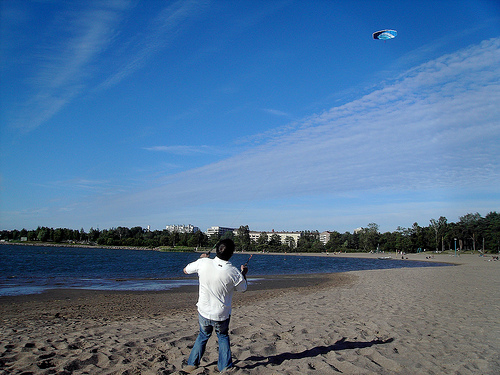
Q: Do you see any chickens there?
A: No, there are no chickens.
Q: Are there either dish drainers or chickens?
A: No, there are no chickens or dish drainers.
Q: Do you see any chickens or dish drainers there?
A: No, there are no chickens or dish drainers.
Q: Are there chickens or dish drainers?
A: No, there are no chickens or dish drainers.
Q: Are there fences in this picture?
A: No, there are no fences.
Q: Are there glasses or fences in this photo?
A: No, there are no fences or glasses.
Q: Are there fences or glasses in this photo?
A: No, there are no fences or glasses.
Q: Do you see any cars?
A: No, there are no cars.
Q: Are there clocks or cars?
A: No, there are no cars or clocks.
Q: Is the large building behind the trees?
A: Yes, the building is behind the trees.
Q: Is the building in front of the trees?
A: No, the building is behind the trees.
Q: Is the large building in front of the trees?
A: No, the building is behind the trees.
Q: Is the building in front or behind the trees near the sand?
A: The building is behind the trees.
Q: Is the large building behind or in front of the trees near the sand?
A: The building is behind the trees.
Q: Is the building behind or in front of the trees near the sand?
A: The building is behind the trees.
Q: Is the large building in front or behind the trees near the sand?
A: The building is behind the trees.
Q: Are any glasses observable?
A: No, there are no glasses.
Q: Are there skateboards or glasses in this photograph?
A: No, there are no glasses or skateboards.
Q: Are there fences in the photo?
A: No, there are no fences.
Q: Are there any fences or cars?
A: No, there are no fences or cars.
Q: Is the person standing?
A: Yes, the person is standing.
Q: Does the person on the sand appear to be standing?
A: Yes, the person is standing.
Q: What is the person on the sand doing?
A: The person is standing.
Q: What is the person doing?
A: The person is standing.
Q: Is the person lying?
A: No, the person is standing.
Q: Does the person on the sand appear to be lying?
A: No, the person is standing.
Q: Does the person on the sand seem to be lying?
A: No, the person is standing.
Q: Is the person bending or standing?
A: The person is standing.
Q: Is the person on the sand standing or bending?
A: The person is standing.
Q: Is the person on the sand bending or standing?
A: The person is standing.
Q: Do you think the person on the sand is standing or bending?
A: The person is standing.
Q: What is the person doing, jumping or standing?
A: The person is standing.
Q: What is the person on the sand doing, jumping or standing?
A: The person is standing.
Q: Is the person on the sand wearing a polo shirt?
A: Yes, the person is wearing a polo shirt.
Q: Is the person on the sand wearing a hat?
A: No, the person is wearing a polo shirt.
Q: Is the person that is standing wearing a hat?
A: No, the person is wearing a polo shirt.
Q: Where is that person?
A: The person is on the sand.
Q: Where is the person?
A: The person is on the sand.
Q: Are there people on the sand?
A: Yes, there is a person on the sand.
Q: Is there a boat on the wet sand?
A: No, there is a person on the sand.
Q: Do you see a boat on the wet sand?
A: No, there is a person on the sand.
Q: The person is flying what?
A: The person is flying the kite.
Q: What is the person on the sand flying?
A: The person is flying the kite.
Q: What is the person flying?
A: The person is flying the kite.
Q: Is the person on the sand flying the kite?
A: Yes, the person is flying the kite.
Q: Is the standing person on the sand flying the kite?
A: Yes, the person is flying the kite.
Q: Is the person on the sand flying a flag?
A: No, the person is flying the kite.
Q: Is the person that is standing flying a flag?
A: No, the person is flying the kite.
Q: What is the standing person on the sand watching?
A: The person is watching the kite.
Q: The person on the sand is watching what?
A: The person is watching the kite.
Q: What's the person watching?
A: The person is watching the kite.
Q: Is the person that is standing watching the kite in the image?
A: Yes, the person is watching the kite.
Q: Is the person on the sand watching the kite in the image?
A: Yes, the person is watching the kite.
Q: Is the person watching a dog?
A: No, the person is watching the kite.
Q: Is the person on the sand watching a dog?
A: No, the person is watching the kite.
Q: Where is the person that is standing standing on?
A: The person is standing on the sand.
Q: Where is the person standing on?
A: The person is standing on the sand.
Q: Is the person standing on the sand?
A: Yes, the person is standing on the sand.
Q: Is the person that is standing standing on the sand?
A: Yes, the person is standing on the sand.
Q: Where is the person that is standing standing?
A: The person is standing in the sand.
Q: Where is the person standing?
A: The person is standing in the sand.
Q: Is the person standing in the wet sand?
A: Yes, the person is standing in the sand.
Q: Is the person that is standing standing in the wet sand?
A: Yes, the person is standing in the sand.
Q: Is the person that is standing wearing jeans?
A: Yes, the person is wearing jeans.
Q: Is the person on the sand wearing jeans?
A: Yes, the person is wearing jeans.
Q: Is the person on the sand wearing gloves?
A: No, the person is wearing jeans.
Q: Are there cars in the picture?
A: No, there are no cars.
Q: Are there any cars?
A: No, there are no cars.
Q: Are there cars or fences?
A: No, there are no cars or fences.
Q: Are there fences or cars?
A: No, there are no cars or fences.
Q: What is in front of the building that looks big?
A: The trees are in front of the building.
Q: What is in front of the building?
A: The trees are in front of the building.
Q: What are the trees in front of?
A: The trees are in front of the building.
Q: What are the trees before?
A: The trees are in front of the building.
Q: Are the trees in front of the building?
A: Yes, the trees are in front of the building.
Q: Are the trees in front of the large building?
A: Yes, the trees are in front of the building.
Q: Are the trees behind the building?
A: No, the trees are in front of the building.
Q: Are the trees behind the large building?
A: No, the trees are in front of the building.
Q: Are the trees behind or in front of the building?
A: The trees are in front of the building.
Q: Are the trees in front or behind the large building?
A: The trees are in front of the building.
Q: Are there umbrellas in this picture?
A: No, there are no umbrellas.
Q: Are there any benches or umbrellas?
A: No, there are no umbrellas or benches.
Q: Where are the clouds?
A: The clouds are in the sky.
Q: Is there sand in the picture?
A: Yes, there is sand.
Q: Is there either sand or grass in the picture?
A: Yes, there is sand.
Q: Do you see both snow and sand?
A: No, there is sand but no snow.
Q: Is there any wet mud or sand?
A: Yes, there is wet sand.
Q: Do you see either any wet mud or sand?
A: Yes, there is wet sand.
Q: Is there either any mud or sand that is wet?
A: Yes, the sand is wet.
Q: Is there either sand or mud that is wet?
A: Yes, the sand is wet.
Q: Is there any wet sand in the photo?
A: Yes, there is wet sand.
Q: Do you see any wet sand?
A: Yes, there is wet sand.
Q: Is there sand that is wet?
A: Yes, there is sand that is wet.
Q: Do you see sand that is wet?
A: Yes, there is sand that is wet.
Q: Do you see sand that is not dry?
A: Yes, there is wet sand.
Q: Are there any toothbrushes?
A: No, there are no toothbrushes.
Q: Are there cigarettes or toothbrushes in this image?
A: No, there are no toothbrushes or cigarettes.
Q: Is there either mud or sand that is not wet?
A: No, there is sand but it is wet.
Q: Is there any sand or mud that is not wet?
A: No, there is sand but it is wet.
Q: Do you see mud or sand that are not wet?
A: No, there is sand but it is wet.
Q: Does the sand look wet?
A: Yes, the sand is wet.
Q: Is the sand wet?
A: Yes, the sand is wet.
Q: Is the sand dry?
A: No, the sand is wet.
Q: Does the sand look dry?
A: No, the sand is wet.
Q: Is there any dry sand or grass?
A: No, there is sand but it is wet.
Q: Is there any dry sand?
A: No, there is sand but it is wet.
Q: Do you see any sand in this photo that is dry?
A: No, there is sand but it is wet.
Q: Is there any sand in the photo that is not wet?
A: No, there is sand but it is wet.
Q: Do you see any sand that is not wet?
A: No, there is sand but it is wet.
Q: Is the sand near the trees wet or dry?
A: The sand is wet.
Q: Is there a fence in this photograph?
A: No, there are no fences.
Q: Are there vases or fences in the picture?
A: No, there are no fences or vases.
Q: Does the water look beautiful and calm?
A: Yes, the water is beautiful and calm.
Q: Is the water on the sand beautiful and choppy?
A: No, the water is beautiful but calm.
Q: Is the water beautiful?
A: Yes, the water is beautiful.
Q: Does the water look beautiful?
A: Yes, the water is beautiful.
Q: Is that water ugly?
A: No, the water is beautiful.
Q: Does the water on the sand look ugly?
A: No, the water is beautiful.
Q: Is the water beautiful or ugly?
A: The water is beautiful.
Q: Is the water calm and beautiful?
A: Yes, the water is calm and beautiful.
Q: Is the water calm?
A: Yes, the water is calm.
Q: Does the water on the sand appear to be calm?
A: Yes, the water is calm.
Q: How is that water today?
A: The water is calm.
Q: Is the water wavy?
A: No, the water is calm.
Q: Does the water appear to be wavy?
A: No, the water is calm.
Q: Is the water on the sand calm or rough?
A: The water is calm.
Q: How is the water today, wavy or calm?
A: The water is calm.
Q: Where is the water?
A: The water is on the sand.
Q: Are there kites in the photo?
A: Yes, there is a kite.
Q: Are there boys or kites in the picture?
A: Yes, there is a kite.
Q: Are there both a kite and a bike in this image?
A: No, there is a kite but no bikes.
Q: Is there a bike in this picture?
A: No, there are no bikes.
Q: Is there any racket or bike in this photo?
A: No, there are no bikes or rackets.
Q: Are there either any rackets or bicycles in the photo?
A: No, there are no bicycles or rackets.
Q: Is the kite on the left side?
A: No, the kite is on the right of the image.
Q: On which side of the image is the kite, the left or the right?
A: The kite is on the right of the image.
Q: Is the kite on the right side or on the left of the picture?
A: The kite is on the right of the image.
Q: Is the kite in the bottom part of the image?
A: No, the kite is in the top of the image.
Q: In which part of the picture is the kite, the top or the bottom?
A: The kite is in the top of the image.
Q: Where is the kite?
A: The kite is in the sky.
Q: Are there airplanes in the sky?
A: No, there is a kite in the sky.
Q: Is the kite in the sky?
A: Yes, the kite is in the sky.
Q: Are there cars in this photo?
A: No, there are no cars.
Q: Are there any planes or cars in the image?
A: No, there are no cars or planes.